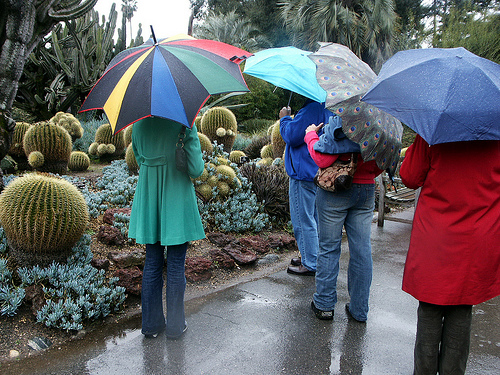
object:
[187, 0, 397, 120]
trees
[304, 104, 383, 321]
woman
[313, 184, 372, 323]
jeans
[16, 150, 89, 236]
cactus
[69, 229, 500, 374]
plane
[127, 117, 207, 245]
coat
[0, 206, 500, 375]
sidewalk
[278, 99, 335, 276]
man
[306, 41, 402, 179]
umbrella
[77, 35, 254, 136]
umbrella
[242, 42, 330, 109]
umbrella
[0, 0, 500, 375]
garden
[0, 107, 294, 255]
cactus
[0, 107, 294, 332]
plants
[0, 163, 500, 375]
ground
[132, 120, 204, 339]
person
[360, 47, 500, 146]
blue umbrella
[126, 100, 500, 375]
people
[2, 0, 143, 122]
cactus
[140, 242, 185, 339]
jeans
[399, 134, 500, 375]
person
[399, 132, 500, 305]
coat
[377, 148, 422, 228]
bench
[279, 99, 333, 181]
coat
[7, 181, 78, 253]
needles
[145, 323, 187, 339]
shoes